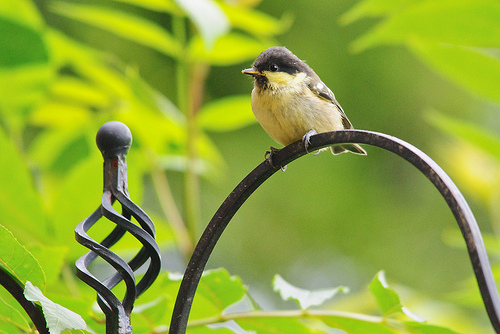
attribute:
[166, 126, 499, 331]
arch — black, metal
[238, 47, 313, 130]
finch — yellow breasted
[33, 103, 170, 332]
pole — black, metal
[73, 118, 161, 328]
metal — woven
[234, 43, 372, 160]
bird — small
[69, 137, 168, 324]
iron — wrought, twisted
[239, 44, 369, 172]
bird — small, little, gray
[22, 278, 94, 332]
leaf — green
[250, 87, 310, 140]
belly — yellow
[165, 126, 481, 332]
wire structure — wrought iron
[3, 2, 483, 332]
background — blurred, green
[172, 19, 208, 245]
stock — slender, long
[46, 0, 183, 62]
leaf — long, green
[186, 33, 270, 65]
leaf — long, green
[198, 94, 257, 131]
leaf — long, green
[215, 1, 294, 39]
leaf — long, green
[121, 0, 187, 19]
leaf — long, green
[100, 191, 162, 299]
twist — double strand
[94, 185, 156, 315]
twist — double strand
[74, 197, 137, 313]
twist — double strand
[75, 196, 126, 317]
twist — double strand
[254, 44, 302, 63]
bonnet — grayish black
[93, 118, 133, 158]
top — ball shaped